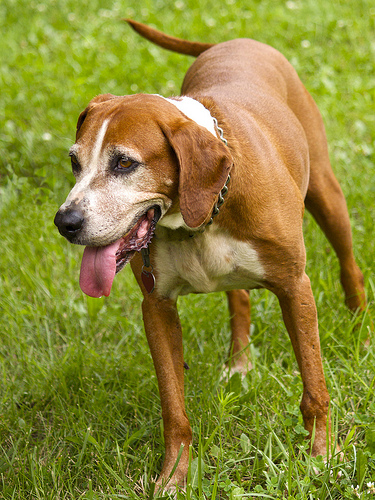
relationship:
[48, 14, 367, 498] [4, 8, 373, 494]
dog on grass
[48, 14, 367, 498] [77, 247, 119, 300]
dog has tongue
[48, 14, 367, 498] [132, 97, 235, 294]
dog has collar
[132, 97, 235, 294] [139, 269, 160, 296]
collar has heart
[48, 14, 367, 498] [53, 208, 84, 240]
dog has nose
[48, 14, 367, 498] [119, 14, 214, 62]
dog has tail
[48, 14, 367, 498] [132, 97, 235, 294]
dog wearing collar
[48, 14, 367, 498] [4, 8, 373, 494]
dog standing on grass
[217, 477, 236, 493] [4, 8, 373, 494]
clover on grass